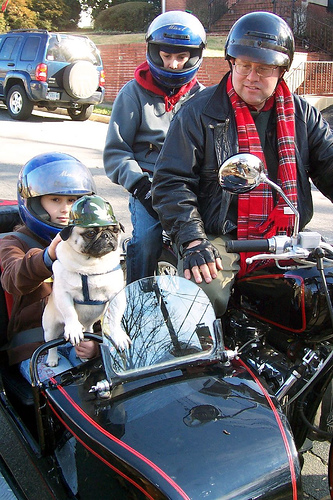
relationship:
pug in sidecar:
[37, 195, 133, 367] [1, 192, 301, 499]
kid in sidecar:
[0, 149, 105, 347] [1, 192, 301, 499]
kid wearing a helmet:
[0, 149, 105, 347] [11, 147, 104, 237]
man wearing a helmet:
[150, 14, 332, 284] [216, 16, 315, 102]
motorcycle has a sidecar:
[134, 219, 333, 479] [1, 192, 301, 499]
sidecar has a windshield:
[1, 192, 301, 499] [95, 275, 232, 383]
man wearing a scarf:
[150, 14, 332, 284] [219, 73, 310, 270]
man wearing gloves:
[150, 14, 332, 284] [178, 243, 230, 287]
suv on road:
[1, 30, 108, 124] [0, 101, 333, 239]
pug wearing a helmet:
[37, 195, 133, 367] [63, 196, 127, 239]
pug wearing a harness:
[37, 195, 133, 367] [59, 257, 126, 312]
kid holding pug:
[0, 149, 105, 347] [37, 195, 133, 367]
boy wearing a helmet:
[102, 12, 212, 275] [142, 8, 206, 86]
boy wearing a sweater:
[102, 12, 212, 275] [108, 83, 209, 199]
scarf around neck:
[219, 73, 310, 270] [229, 86, 284, 122]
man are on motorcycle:
[150, 13, 331, 321] [134, 219, 333, 479]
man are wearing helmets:
[150, 13, 331, 321] [137, 11, 304, 102]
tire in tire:
[67, 60, 100, 101] [67, 60, 100, 101]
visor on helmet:
[28, 156, 99, 205] [11, 147, 104, 237]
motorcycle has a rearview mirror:
[134, 219, 333, 479] [217, 154, 269, 194]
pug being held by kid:
[37, 195, 133, 367] [0, 149, 105, 347]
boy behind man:
[102, 12, 212, 275] [150, 14, 332, 284]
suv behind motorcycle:
[1, 30, 108, 124] [134, 219, 333, 479]